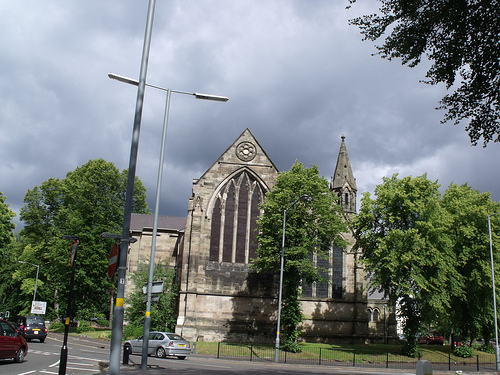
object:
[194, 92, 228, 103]
street light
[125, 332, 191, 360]
car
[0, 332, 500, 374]
street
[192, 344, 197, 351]
light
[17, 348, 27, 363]
tire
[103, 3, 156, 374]
pole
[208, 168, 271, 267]
windows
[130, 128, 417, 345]
church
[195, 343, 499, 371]
fence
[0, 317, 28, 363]
car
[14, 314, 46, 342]
car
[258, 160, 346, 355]
tree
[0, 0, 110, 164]
sky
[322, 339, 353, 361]
grass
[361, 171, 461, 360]
trees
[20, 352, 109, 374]
lines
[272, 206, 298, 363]
post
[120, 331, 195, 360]
cars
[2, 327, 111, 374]
intersection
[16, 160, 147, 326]
tree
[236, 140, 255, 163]
circle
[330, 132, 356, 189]
steeple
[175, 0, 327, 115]
clouds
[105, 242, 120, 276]
sign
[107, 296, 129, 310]
stripes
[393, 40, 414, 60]
leaves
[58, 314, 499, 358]
corner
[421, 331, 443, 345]
car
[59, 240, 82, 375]
pole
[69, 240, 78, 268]
sign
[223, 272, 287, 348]
shadow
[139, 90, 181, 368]
pole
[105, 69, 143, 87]
lights